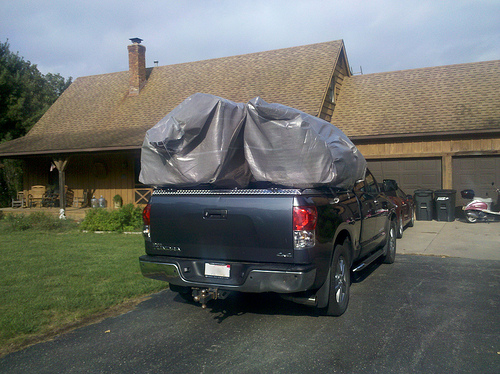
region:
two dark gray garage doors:
[344, 152, 495, 214]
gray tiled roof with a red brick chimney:
[1, 33, 341, 155]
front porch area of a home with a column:
[0, 127, 142, 212]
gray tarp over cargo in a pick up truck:
[136, 89, 368, 189]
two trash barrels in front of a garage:
[411, 185, 458, 222]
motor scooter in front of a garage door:
[456, 185, 495, 225]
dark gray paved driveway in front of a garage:
[0, 214, 497, 373]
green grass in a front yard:
[0, 224, 176, 369]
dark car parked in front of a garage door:
[364, 179, 423, 236]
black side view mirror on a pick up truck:
[376, 177, 400, 195]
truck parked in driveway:
[131, 95, 407, 320]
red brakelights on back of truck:
[134, 194, 321, 259]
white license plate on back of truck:
[195, 257, 239, 282]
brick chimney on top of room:
[119, 33, 159, 99]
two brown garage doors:
[358, 147, 498, 219]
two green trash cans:
[411, 183, 458, 226]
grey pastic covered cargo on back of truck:
[124, 88, 376, 201]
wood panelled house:
[17, 162, 163, 210]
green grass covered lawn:
[4, 208, 164, 338]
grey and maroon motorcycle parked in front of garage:
[454, 189, 496, 226]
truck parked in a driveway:
[128, 93, 406, 287]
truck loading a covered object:
[139, 80, 350, 190]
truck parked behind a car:
[123, 113, 493, 271]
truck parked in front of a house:
[151, 94, 434, 342]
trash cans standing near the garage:
[410, 168, 472, 231]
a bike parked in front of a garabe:
[459, 171, 495, 228]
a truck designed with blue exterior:
[106, 165, 381, 332]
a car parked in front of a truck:
[385, 182, 427, 243]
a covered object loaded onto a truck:
[155, 96, 365, 248]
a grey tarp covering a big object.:
[121, 111, 411, 254]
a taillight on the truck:
[288, 199, 318, 257]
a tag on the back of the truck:
[203, 255, 232, 280]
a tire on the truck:
[328, 249, 352, 320]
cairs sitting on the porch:
[16, 186, 51, 208]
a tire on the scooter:
[463, 204, 481, 227]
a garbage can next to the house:
[433, 179, 459, 230]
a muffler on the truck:
[281, 281, 328, 317]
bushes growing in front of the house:
[85, 204, 115, 235]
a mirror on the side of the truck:
[372, 168, 401, 195]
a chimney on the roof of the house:
[123, 33, 154, 100]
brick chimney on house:
[128, 34, 147, 96]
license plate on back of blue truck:
[200, 258, 233, 279]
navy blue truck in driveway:
[141, 162, 398, 318]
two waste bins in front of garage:
[411, 184, 458, 221]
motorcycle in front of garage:
[455, 185, 498, 222]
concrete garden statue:
[57, 205, 67, 220]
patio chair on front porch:
[24, 180, 46, 205]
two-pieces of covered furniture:
[135, 90, 369, 192]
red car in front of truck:
[380, 184, 418, 237]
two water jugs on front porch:
[85, 192, 109, 209]